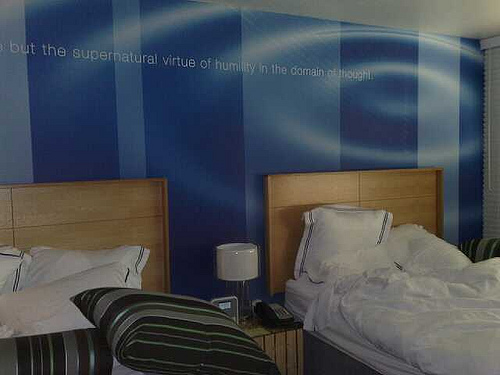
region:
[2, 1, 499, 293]
the blue striped wall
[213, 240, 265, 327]
the lamp on the night stand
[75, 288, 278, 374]
the black pillow with stripes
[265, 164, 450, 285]
the bed's head board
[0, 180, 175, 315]
the wooden head board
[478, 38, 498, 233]
a part of the horizontal blinds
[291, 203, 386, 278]
the white pillow on the bed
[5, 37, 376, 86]
the words on the wall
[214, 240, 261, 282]
the white lamp shade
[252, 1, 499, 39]
the white ceiling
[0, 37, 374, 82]
White writing on the blue striped wall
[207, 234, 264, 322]
Lamp with white shade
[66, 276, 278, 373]
Black and gray striped pillow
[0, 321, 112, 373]
Black and silver striped pillow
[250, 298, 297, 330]
Black and silver phone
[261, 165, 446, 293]
Light brown wooden headboard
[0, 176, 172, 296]
Light brown wooden headboard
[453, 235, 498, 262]
Black and silver striped pillow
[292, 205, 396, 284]
Square white pillow with black stripes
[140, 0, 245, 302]
Dark blue stripe on the wall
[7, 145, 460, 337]
Cot is brown color.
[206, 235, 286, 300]
Lamp is white color.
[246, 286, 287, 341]
Phone is black color.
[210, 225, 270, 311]
lamp is between the cot.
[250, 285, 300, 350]
Phone is in the table.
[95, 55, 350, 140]
Wall is blue color.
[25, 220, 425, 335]
Pillows are in cot.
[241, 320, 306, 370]
table is brown color.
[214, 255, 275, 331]
Lamp is in the table.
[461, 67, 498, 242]
Window screen is white color.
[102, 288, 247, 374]
the pillow is stripped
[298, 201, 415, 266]
the matress is white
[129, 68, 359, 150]
the wall is blue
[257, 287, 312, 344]
the telephone is black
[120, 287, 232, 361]
the strips are blue and black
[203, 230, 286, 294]
the light stand is white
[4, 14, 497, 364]
the scene is in a hotel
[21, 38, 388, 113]
the letters are in white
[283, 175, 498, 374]
the bed is unspread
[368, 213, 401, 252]
the strip is black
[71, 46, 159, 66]
the word supernatural in white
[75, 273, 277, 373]
a black and grey stripped pillow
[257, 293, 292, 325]
a black landline phone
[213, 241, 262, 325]
a white shade lamp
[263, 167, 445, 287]
a light brown wood headboard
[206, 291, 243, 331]
a white and grey clock radio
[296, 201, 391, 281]
a white pillow with a black boarder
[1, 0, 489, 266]
a vertical blue stripped wall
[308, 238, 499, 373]
a white messy comforter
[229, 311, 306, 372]
a light wooden night stand